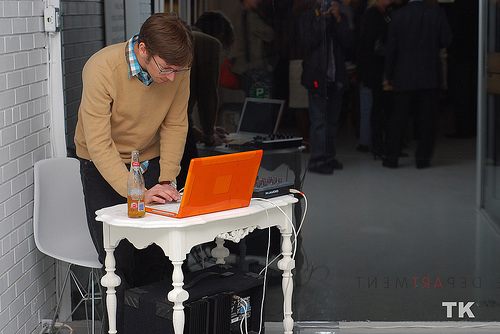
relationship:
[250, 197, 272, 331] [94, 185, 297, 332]
cord leading from table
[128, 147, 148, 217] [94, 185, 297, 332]
bottle on table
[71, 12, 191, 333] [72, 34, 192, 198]
man wearing sweater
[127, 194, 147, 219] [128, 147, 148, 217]
liquid in bottle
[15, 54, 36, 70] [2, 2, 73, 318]
brick on wall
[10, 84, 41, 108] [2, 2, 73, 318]
brick on wall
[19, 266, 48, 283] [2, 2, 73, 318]
brick on wall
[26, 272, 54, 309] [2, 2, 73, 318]
brick on wall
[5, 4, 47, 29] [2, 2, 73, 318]
brick on wall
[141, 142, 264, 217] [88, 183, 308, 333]
laptop on desk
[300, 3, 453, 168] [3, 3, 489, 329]
people standing in building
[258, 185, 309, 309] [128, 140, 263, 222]
cords connected to laptop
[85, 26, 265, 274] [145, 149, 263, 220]
man looking at laptop